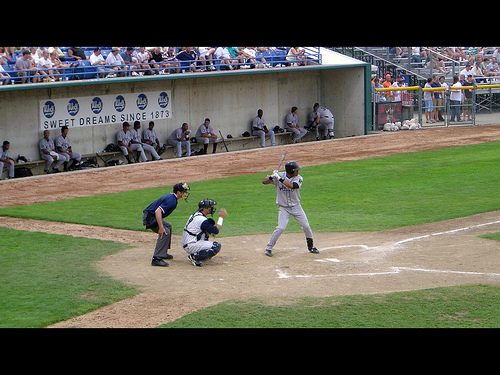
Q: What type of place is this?
A: It is a field.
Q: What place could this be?
A: It is a field.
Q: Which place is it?
A: It is a field.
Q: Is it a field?
A: Yes, it is a field.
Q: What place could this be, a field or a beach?
A: It is a field.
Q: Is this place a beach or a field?
A: It is a field.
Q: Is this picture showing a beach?
A: No, the picture is showing a field.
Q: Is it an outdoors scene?
A: Yes, it is outdoors.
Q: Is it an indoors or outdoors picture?
A: It is outdoors.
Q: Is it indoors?
A: No, it is outdoors.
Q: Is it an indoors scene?
A: No, it is outdoors.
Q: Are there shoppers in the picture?
A: No, there are no shoppers.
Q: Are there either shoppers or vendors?
A: No, there are no shoppers or vendors.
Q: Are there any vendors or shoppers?
A: No, there are no shoppers or vendors.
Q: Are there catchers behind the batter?
A: Yes, there is a catcher behind the batter.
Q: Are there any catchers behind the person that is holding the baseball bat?
A: Yes, there is a catcher behind the batter.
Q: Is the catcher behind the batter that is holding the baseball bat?
A: Yes, the catcher is behind the batter.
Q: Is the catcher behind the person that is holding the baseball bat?
A: Yes, the catcher is behind the batter.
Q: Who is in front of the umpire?
A: The catcher is in front of the umpire.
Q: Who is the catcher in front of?
A: The catcher is in front of the umpire.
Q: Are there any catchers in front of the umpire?
A: Yes, there is a catcher in front of the umpire.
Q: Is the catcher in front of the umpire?
A: Yes, the catcher is in front of the umpire.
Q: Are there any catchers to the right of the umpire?
A: Yes, there is a catcher to the right of the umpire.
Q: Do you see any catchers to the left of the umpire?
A: No, the catcher is to the right of the umpire.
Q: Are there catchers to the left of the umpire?
A: No, the catcher is to the right of the umpire.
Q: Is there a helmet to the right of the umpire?
A: No, there is a catcher to the right of the umpire.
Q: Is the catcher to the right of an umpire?
A: Yes, the catcher is to the right of an umpire.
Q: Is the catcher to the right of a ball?
A: No, the catcher is to the right of an umpire.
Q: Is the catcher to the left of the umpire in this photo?
A: No, the catcher is to the right of the umpire.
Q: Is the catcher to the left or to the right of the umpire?
A: The catcher is to the right of the umpire.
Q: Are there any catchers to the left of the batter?
A: Yes, there is a catcher to the left of the batter.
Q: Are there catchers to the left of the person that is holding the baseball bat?
A: Yes, there is a catcher to the left of the batter.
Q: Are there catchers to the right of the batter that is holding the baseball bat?
A: No, the catcher is to the left of the batter.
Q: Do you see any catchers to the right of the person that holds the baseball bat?
A: No, the catcher is to the left of the batter.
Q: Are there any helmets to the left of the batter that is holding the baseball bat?
A: No, there is a catcher to the left of the batter.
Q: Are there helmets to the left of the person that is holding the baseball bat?
A: No, there is a catcher to the left of the batter.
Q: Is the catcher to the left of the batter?
A: Yes, the catcher is to the left of the batter.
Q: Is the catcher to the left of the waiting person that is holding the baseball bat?
A: Yes, the catcher is to the left of the batter.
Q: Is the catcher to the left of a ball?
A: No, the catcher is to the left of the batter.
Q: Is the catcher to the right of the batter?
A: No, the catcher is to the left of the batter.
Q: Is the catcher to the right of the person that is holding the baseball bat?
A: No, the catcher is to the left of the batter.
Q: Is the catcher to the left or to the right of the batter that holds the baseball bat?
A: The catcher is to the left of the batter.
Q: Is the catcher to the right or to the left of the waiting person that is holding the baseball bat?
A: The catcher is to the left of the batter.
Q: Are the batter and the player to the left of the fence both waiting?
A: Yes, both the batter and the player are waiting.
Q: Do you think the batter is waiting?
A: Yes, the batter is waiting.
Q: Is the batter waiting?
A: Yes, the batter is waiting.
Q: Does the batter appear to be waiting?
A: Yes, the batter is waiting.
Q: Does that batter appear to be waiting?
A: Yes, the batter is waiting.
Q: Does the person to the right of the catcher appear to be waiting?
A: Yes, the batter is waiting.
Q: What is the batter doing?
A: The batter is waiting.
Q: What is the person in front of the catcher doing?
A: The batter is waiting.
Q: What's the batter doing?
A: The batter is waiting.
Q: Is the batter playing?
A: No, the batter is waiting.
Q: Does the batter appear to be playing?
A: No, the batter is waiting.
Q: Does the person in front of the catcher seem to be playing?
A: No, the batter is waiting.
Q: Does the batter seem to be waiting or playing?
A: The batter is waiting.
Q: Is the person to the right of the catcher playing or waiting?
A: The batter is waiting.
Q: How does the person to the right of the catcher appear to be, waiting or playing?
A: The batter is waiting.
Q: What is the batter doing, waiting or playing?
A: The batter is waiting.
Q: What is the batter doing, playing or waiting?
A: The batter is waiting.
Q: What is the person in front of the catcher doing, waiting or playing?
A: The batter is waiting.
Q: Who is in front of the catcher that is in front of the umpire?
A: The batter is in front of the catcher.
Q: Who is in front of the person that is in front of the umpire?
A: The batter is in front of the catcher.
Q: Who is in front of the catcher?
A: The batter is in front of the catcher.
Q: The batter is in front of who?
A: The batter is in front of the catcher.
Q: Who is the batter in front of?
A: The batter is in front of the catcher.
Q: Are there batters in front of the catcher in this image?
A: Yes, there is a batter in front of the catcher.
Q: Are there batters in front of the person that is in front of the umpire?
A: Yes, there is a batter in front of the catcher.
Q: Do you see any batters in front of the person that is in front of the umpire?
A: Yes, there is a batter in front of the catcher.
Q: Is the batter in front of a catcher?
A: Yes, the batter is in front of a catcher.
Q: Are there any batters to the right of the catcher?
A: Yes, there is a batter to the right of the catcher.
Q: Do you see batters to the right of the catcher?
A: Yes, there is a batter to the right of the catcher.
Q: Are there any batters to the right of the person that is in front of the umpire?
A: Yes, there is a batter to the right of the catcher.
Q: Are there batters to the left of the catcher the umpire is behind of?
A: No, the batter is to the right of the catcher.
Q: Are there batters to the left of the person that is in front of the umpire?
A: No, the batter is to the right of the catcher.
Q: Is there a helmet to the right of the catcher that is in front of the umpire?
A: No, there is a batter to the right of the catcher.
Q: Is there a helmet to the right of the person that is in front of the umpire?
A: No, there is a batter to the right of the catcher.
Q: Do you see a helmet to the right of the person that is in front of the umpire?
A: No, there is a batter to the right of the catcher.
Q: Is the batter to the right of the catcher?
A: Yes, the batter is to the right of the catcher.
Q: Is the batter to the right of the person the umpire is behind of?
A: Yes, the batter is to the right of the catcher.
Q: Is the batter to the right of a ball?
A: No, the batter is to the right of the catcher.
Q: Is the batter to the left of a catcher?
A: No, the batter is to the right of a catcher.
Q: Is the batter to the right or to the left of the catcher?
A: The batter is to the right of the catcher.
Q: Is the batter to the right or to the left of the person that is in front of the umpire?
A: The batter is to the right of the catcher.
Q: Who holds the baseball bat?
A: The batter holds the baseball bat.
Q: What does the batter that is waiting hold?
A: The batter holds the baseball bat.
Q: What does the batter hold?
A: The batter holds the baseball bat.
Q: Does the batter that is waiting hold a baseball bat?
A: Yes, the batter holds a baseball bat.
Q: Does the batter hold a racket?
A: No, the batter holds a baseball bat.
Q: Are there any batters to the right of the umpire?
A: Yes, there is a batter to the right of the umpire.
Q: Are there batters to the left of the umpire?
A: No, the batter is to the right of the umpire.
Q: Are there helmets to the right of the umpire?
A: No, there is a batter to the right of the umpire.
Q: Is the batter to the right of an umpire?
A: Yes, the batter is to the right of an umpire.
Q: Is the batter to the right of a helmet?
A: No, the batter is to the right of an umpire.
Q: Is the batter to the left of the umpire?
A: No, the batter is to the right of the umpire.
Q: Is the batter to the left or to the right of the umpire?
A: The batter is to the right of the umpire.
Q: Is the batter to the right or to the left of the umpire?
A: The batter is to the right of the umpire.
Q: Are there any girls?
A: No, there are no girls.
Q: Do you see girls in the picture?
A: No, there are no girls.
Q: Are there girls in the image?
A: No, there are no girls.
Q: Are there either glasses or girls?
A: No, there are no girls or glasses.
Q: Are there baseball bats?
A: Yes, there is a baseball bat.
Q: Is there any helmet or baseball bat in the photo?
A: Yes, there is a baseball bat.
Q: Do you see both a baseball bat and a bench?
A: Yes, there are both a baseball bat and a bench.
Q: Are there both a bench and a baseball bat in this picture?
A: Yes, there are both a baseball bat and a bench.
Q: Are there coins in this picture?
A: No, there are no coins.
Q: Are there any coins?
A: No, there are no coins.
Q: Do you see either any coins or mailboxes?
A: No, there are no coins or mailboxes.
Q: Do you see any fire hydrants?
A: No, there are no fire hydrants.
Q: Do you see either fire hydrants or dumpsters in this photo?
A: No, there are no fire hydrants or dumpsters.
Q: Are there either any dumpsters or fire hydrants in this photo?
A: No, there are no fire hydrants or dumpsters.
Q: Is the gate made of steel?
A: Yes, the gate is made of steel.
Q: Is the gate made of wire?
A: No, the gate is made of steel.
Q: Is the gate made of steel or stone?
A: The gate is made of steel.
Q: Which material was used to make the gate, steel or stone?
A: The gate is made of steel.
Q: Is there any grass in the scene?
A: Yes, there is grass.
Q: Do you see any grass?
A: Yes, there is grass.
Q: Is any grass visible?
A: Yes, there is grass.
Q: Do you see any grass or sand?
A: Yes, there is grass.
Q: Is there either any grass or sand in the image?
A: Yes, there is grass.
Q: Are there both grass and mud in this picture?
A: No, there is grass but no mud.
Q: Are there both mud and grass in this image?
A: No, there is grass but no mud.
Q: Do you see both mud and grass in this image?
A: No, there is grass but no mud.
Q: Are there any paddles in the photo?
A: No, there are no paddles.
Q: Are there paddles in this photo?
A: No, there are no paddles.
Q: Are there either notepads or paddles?
A: No, there are no paddles or notepads.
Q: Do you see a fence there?
A: Yes, there is a fence.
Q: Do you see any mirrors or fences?
A: Yes, there is a fence.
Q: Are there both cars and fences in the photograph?
A: No, there is a fence but no cars.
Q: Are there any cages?
A: No, there are no cages.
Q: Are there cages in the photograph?
A: No, there are no cages.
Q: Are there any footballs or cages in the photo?
A: No, there are no cages or footballs.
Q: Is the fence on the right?
A: Yes, the fence is on the right of the image.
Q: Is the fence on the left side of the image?
A: No, the fence is on the right of the image.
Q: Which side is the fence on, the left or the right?
A: The fence is on the right of the image.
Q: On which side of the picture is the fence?
A: The fence is on the right of the image.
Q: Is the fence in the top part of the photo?
A: Yes, the fence is in the top of the image.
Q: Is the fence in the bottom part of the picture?
A: No, the fence is in the top of the image.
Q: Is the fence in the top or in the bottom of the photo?
A: The fence is in the top of the image.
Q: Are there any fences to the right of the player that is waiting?
A: Yes, there is a fence to the right of the player.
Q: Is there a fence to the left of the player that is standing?
A: No, the fence is to the right of the player.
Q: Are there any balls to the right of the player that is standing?
A: No, there is a fence to the right of the player.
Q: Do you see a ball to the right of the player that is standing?
A: No, there is a fence to the right of the player.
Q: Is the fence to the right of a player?
A: Yes, the fence is to the right of a player.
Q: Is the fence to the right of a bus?
A: No, the fence is to the right of a player.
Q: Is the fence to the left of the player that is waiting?
A: No, the fence is to the right of the player.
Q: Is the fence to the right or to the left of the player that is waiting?
A: The fence is to the right of the player.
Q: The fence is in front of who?
A: The fence is in front of the spectator.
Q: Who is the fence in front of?
A: The fence is in front of the spectator.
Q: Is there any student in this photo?
A: No, there are no students.